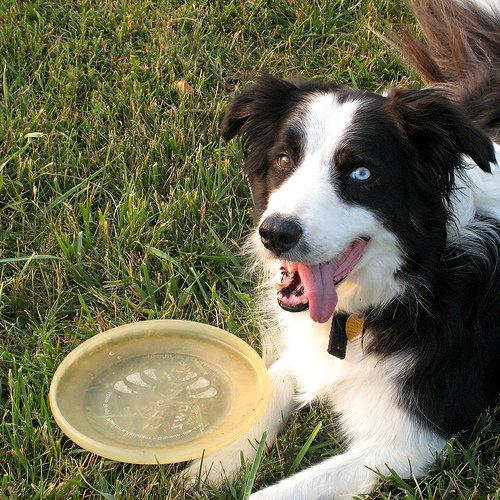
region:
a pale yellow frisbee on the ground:
[45, 313, 271, 464]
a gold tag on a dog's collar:
[343, 308, 368, 345]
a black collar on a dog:
[324, 199, 450, 363]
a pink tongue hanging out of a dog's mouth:
[298, 259, 339, 329]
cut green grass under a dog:
[1, 0, 499, 497]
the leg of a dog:
[171, 357, 296, 494]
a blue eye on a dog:
[347, 165, 373, 183]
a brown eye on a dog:
[273, 151, 293, 168]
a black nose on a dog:
[256, 216, 301, 251]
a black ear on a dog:
[404, 87, 499, 168]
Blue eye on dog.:
[341, 156, 379, 186]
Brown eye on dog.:
[267, 143, 297, 173]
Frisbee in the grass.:
[47, 315, 274, 471]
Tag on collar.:
[339, 311, 369, 344]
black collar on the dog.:
[323, 301, 408, 358]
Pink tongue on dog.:
[290, 254, 342, 329]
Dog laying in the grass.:
[172, 0, 497, 498]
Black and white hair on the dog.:
[170, 0, 498, 496]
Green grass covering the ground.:
[0, 3, 496, 497]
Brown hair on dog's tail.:
[367, 0, 497, 139]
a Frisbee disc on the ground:
[48, 318, 268, 465]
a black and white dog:
[169, 0, 499, 498]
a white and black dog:
[171, 0, 498, 499]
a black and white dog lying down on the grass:
[167, 2, 498, 498]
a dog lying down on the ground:
[46, 1, 498, 498]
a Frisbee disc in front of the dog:
[46, 1, 498, 498]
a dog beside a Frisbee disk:
[47, 2, 498, 498]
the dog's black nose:
[258, 216, 304, 257]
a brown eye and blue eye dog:
[273, 152, 373, 181]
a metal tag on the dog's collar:
[344, 310, 367, 342]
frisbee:
[50, 315, 270, 462]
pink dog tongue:
[291, 260, 331, 320]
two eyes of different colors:
[261, 150, 371, 180]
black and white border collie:
[185, 1, 495, 493]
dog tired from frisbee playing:
[45, 0, 495, 495]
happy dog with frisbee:
[45, 0, 495, 495]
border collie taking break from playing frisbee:
[5, 0, 495, 495]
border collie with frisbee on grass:
[5, 0, 495, 495]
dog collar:
[325, 295, 400, 355]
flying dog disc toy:
[46, 316, 266, 461]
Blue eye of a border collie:
[345, 160, 375, 191]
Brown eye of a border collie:
[269, 145, 295, 173]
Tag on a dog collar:
[342, 299, 367, 345]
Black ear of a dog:
[382, 81, 488, 177]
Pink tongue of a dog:
[299, 260, 334, 327]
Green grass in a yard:
[26, 236, 91, 267]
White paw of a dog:
[173, 465, 243, 495]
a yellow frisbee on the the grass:
[48, 319, 272, 464]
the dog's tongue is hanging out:
[222, 77, 487, 329]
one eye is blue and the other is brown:
[272, 148, 373, 185]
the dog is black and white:
[237, 83, 499, 487]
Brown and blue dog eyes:
[265, 140, 380, 191]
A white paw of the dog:
[165, 422, 275, 492]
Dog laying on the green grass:
[0, 0, 495, 495]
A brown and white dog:
[151, 0, 493, 495]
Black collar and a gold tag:
[316, 285, 412, 370]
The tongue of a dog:
[285, 250, 355, 330]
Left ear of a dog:
[371, 65, 493, 180]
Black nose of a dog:
[241, 201, 311, 266]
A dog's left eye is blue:
[335, 152, 386, 193]